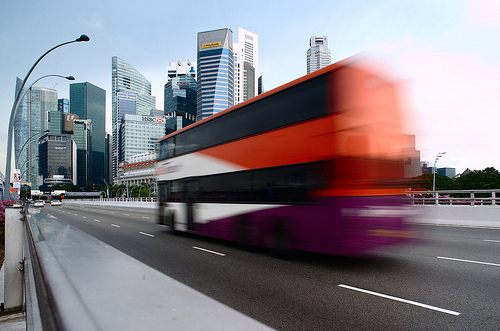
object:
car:
[49, 200, 62, 206]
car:
[33, 200, 44, 208]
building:
[306, 31, 330, 74]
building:
[162, 56, 198, 135]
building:
[121, 109, 171, 167]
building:
[107, 52, 162, 191]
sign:
[202, 40, 222, 49]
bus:
[152, 49, 432, 263]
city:
[4, 24, 334, 205]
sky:
[0, 3, 499, 171]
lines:
[40, 202, 465, 316]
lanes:
[43, 200, 499, 327]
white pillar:
[0, 205, 27, 315]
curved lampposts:
[0, 33, 93, 201]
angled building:
[192, 27, 260, 120]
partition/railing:
[419, 186, 483, 208]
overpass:
[27, 185, 105, 200]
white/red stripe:
[153, 109, 354, 180]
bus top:
[152, 53, 385, 140]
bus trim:
[218, 203, 409, 256]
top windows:
[158, 70, 342, 160]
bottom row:
[157, 159, 335, 208]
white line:
[328, 275, 469, 319]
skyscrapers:
[11, 77, 57, 194]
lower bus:
[203, 193, 410, 253]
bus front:
[152, 137, 214, 235]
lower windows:
[157, 160, 322, 211]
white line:
[189, 240, 228, 258]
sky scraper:
[43, 94, 90, 199]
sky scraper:
[70, 80, 107, 190]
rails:
[444, 200, 497, 203]